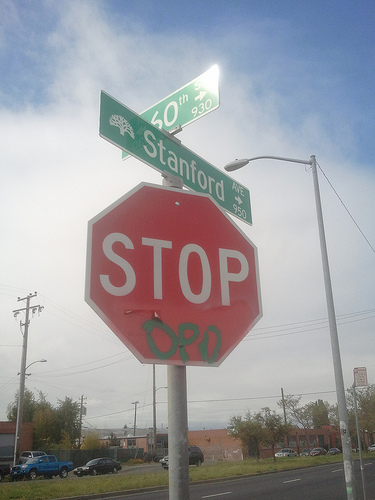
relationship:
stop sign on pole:
[91, 183, 272, 375] [151, 369, 223, 487]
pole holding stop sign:
[151, 369, 223, 487] [91, 183, 272, 375]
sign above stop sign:
[106, 93, 269, 201] [91, 183, 272, 375]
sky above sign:
[198, 12, 336, 100] [106, 93, 269, 201]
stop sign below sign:
[91, 183, 272, 375] [106, 93, 269, 201]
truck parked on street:
[8, 453, 74, 480] [0, 458, 271, 483]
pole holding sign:
[165, 365, 189, 498] [106, 93, 269, 201]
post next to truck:
[11, 289, 45, 463] [8, 453, 74, 480]